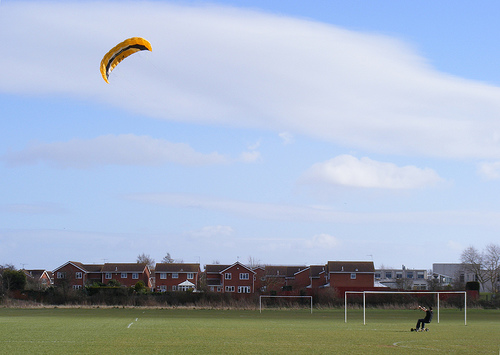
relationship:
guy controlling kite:
[409, 303, 437, 335] [100, 36, 154, 83]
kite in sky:
[100, 36, 154, 83] [0, 1, 500, 271]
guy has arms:
[409, 303, 437, 335] [416, 305, 426, 314]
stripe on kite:
[106, 44, 148, 76] [100, 36, 154, 83]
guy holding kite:
[409, 303, 437, 335] [100, 36, 154, 83]